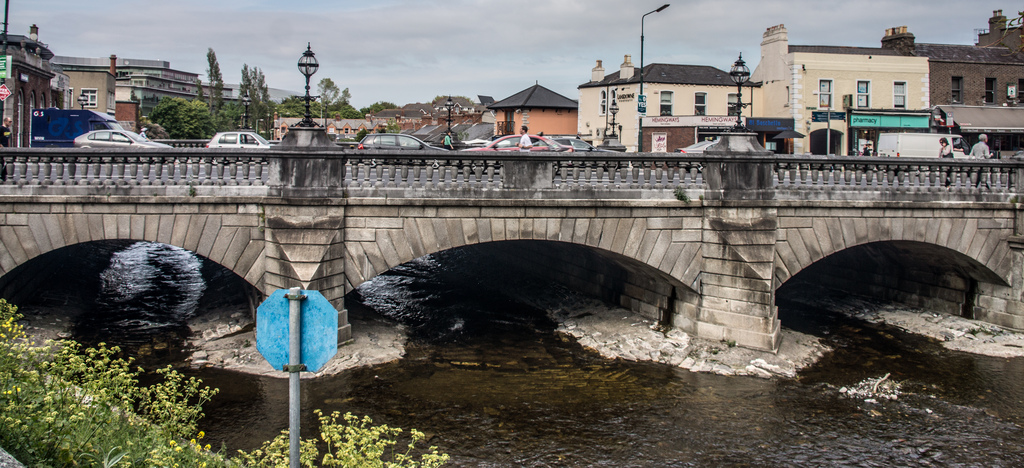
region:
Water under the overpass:
[401, 265, 556, 442]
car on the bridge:
[63, 117, 166, 160]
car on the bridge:
[208, 116, 263, 152]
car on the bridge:
[345, 132, 435, 171]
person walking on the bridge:
[514, 121, 544, 159]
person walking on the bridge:
[969, 129, 990, 172]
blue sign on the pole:
[240, 278, 354, 384]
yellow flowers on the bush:
[56, 334, 193, 440]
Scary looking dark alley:
[351, 222, 712, 346]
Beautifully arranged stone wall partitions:
[376, 206, 572, 235]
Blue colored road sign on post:
[245, 279, 348, 448]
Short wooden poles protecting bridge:
[351, 152, 504, 185]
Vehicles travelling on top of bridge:
[69, 124, 804, 150]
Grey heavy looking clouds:
[359, 18, 566, 66]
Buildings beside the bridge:
[613, 37, 967, 145]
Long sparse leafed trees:
[201, 31, 275, 115]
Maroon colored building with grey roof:
[492, 72, 584, 133]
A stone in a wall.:
[520, 216, 533, 237]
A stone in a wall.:
[528, 213, 544, 236]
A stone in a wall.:
[543, 216, 560, 239]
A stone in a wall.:
[561, 217, 571, 237]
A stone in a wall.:
[575, 213, 594, 242]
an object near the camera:
[24, 331, 452, 465]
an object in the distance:
[292, 34, 327, 115]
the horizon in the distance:
[182, 76, 557, 127]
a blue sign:
[248, 279, 354, 371]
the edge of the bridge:
[2, 131, 1015, 192]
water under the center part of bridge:
[415, 289, 570, 426]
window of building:
[659, 84, 676, 114]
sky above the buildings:
[38, 0, 924, 106]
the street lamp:
[630, 0, 678, 100]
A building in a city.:
[893, 77, 913, 110]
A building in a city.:
[824, 127, 835, 147]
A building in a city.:
[695, 89, 712, 119]